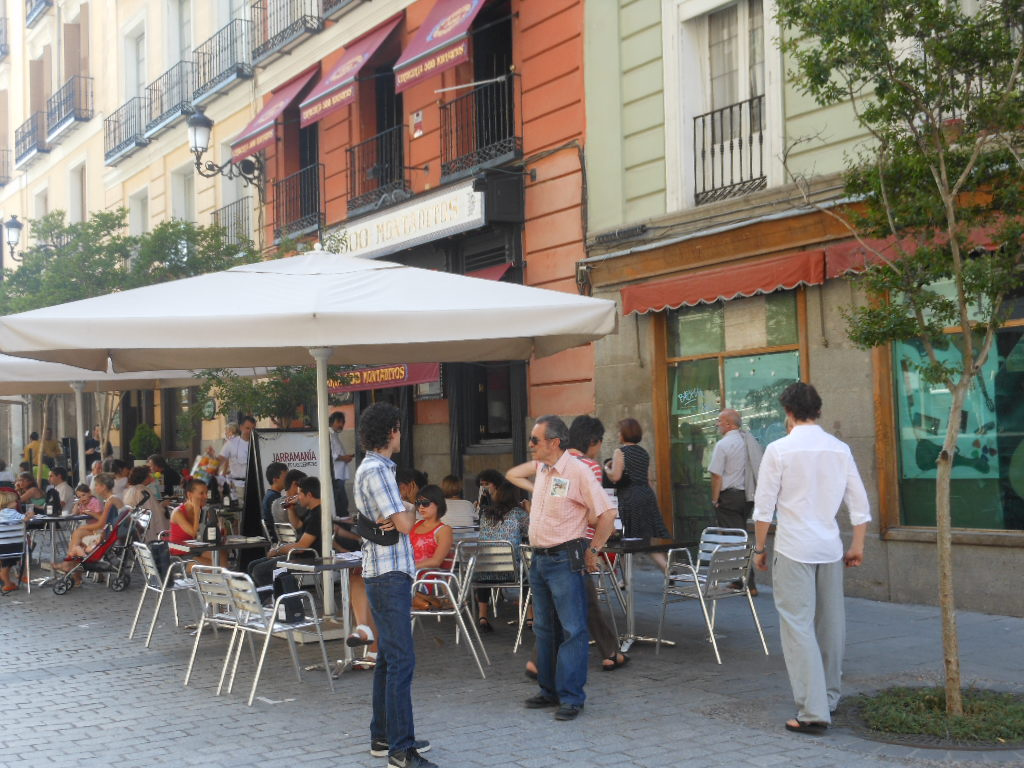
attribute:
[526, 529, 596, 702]
jeans — blue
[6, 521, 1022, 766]
ground — gray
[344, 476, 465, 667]
person — sitting down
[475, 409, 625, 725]
person — standing up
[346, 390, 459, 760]
person — standing up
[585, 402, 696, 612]
person — standing up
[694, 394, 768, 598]
person — standing up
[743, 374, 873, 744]
person — standing up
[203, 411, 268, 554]
person — standing up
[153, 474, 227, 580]
person — sitting down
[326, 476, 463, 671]
person — sitting down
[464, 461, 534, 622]
person — sitting down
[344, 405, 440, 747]
man — standing still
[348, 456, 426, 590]
shirt — plaid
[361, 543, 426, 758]
blue jeans — dark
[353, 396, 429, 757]
man — young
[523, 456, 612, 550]
shirt — light colored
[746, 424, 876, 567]
shirt — white 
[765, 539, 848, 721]
pants — light gray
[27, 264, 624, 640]
umbrella — large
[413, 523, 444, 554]
dress — red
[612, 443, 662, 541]
dress — black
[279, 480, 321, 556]
man — young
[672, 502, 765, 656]
chair — empty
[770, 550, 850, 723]
pants — gray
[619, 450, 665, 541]
dress — black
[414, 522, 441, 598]
shirt — red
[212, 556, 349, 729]
chair — silver, metal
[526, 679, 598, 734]
shoes — black